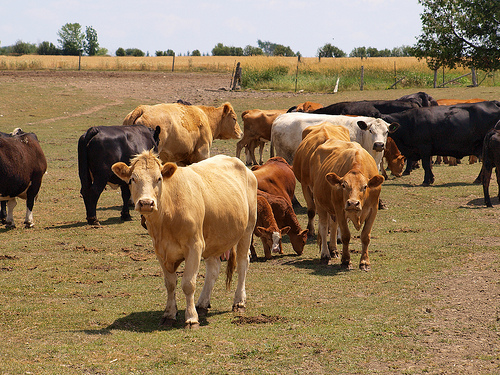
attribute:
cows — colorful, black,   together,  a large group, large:
[4, 92, 496, 310]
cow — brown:
[1, 128, 49, 228]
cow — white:
[267, 108, 391, 182]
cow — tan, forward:
[109, 155, 259, 322]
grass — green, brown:
[7, 77, 499, 372]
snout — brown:
[342, 196, 364, 213]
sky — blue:
[1, 1, 497, 59]